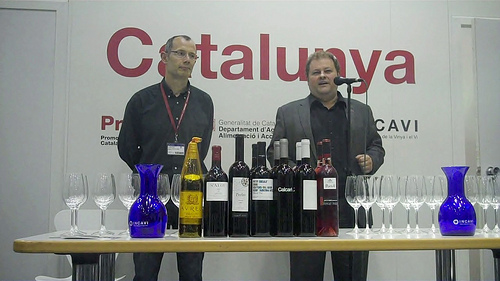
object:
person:
[223, 132, 413, 197]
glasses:
[338, 172, 499, 236]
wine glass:
[345, 175, 367, 235]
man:
[113, 32, 217, 279]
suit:
[276, 93, 378, 278]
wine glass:
[63, 171, 85, 240]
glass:
[346, 172, 370, 236]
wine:
[174, 133, 206, 238]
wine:
[204, 134, 231, 241]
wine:
[230, 127, 254, 236]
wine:
[246, 128, 274, 241]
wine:
[313, 131, 344, 244]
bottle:
[273, 140, 297, 235]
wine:
[272, 136, 298, 236]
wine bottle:
[274, 138, 297, 235]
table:
[15, 225, 499, 249]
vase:
[125, 161, 169, 238]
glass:
[59, 171, 91, 238]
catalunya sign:
[66, 2, 451, 174]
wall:
[67, 0, 494, 277]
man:
[271, 55, 383, 278]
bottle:
[315, 136, 344, 236]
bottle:
[296, 136, 317, 237]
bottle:
[230, 132, 250, 233]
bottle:
[176, 138, 204, 238]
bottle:
[297, 139, 318, 232]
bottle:
[277, 138, 296, 236]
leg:
[68, 252, 103, 279]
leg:
[101, 253, 118, 279]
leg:
[434, 248, 454, 279]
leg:
[491, 248, 498, 278]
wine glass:
[344, 176, 369, 231]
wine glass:
[354, 170, 381, 232]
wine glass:
[156, 170, 172, 202]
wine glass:
[475, 171, 494, 236]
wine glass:
[462, 173, 478, 202]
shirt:
[118, 83, 217, 177]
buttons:
[162, 90, 173, 100]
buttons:
[179, 94, 191, 101]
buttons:
[173, 97, 181, 107]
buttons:
[169, 115, 184, 123]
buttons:
[169, 161, 182, 171]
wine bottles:
[178, 133, 340, 236]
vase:
[436, 162, 479, 237]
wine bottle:
[175, 134, 205, 235]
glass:
[91, 172, 121, 237]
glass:
[116, 170, 141, 237]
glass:
[382, 175, 402, 235]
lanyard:
[157, 83, 189, 160]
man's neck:
[160, 70, 190, 92]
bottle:
[322, 134, 338, 237]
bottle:
[252, 139, 272, 237]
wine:
[201, 142, 231, 233]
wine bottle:
[316, 132, 339, 238]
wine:
[154, 135, 354, 235]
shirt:
[307, 96, 353, 176]